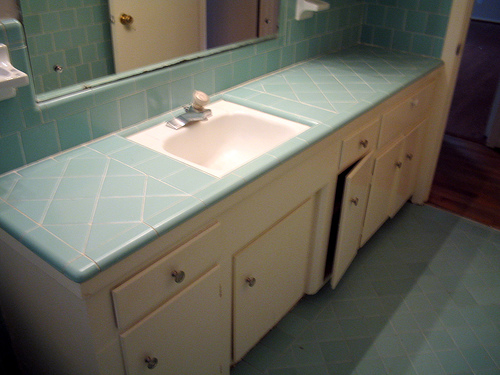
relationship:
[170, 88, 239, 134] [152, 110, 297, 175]
faucet above bathroom sink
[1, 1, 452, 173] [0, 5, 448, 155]
tile on wall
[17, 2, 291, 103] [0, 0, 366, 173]
bathroom mirror on wall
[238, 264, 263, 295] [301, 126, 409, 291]
knob on cabinet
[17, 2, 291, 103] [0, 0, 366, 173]
bathroom mirror attached to wall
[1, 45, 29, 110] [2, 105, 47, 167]
soap holder attached to wall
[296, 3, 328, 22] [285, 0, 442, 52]
holder on wall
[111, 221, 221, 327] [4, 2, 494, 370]
drawer in bathroom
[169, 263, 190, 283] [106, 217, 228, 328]
knob on drawer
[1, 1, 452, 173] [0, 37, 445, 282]
tile on counter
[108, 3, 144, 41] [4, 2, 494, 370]
doorknob in bathroom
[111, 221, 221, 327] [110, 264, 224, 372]
drawer in cabinet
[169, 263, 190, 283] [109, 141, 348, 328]
knob attached to drawer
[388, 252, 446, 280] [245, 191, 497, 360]
tile on floor